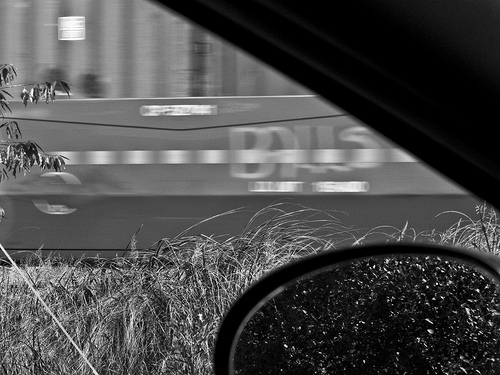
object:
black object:
[235, 252, 500, 374]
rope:
[0, 242, 102, 374]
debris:
[234, 257, 500, 374]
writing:
[137, 103, 220, 117]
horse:
[57, 14, 88, 42]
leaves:
[0, 62, 73, 181]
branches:
[0, 118, 70, 172]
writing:
[226, 123, 389, 180]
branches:
[21, 73, 73, 109]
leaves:
[61, 259, 202, 337]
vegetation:
[1, 202, 500, 374]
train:
[0, 0, 479, 270]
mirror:
[211, 242, 500, 374]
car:
[148, 1, 500, 212]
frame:
[207, 239, 499, 374]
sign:
[57, 15, 86, 41]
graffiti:
[228, 124, 389, 180]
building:
[0, 0, 500, 258]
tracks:
[0, 256, 257, 292]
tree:
[0, 63, 70, 176]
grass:
[0, 195, 499, 372]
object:
[213, 240, 499, 374]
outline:
[213, 239, 500, 373]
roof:
[171, 0, 500, 218]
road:
[81, 103, 421, 196]